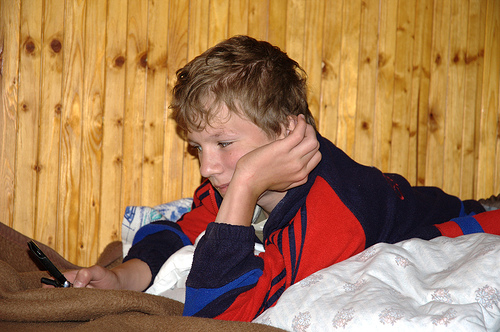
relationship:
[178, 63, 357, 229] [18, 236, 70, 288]
boy holding phone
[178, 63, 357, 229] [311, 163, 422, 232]
boy wearing sweater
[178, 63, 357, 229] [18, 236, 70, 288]
boy on phone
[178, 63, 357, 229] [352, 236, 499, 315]
boy on bed